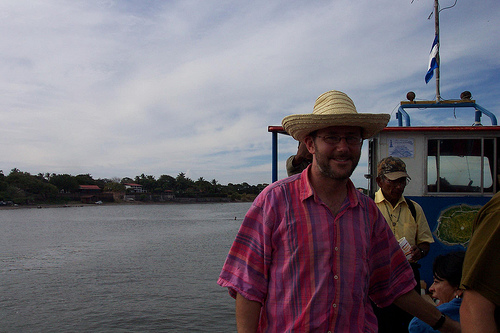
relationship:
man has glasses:
[217, 89, 461, 333] [319, 132, 364, 149]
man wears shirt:
[217, 89, 461, 333] [214, 160, 421, 332]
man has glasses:
[368, 152, 438, 327] [387, 178, 412, 183]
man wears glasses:
[368, 155, 438, 332] [383, 178, 410, 185]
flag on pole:
[423, 32, 440, 84] [431, 0, 440, 99]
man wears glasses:
[203, 68, 420, 329] [319, 132, 376, 146]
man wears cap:
[368, 152, 438, 327] [373, 155, 411, 180]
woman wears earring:
[403, 247, 464, 332] [453, 293, 459, 299]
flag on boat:
[422, 33, 441, 91] [260, 71, 494, 306]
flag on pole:
[424, 32, 436, 82] [436, 5, 441, 107]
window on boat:
[421, 147, 488, 192] [302, 83, 492, 316]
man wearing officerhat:
[203, 68, 420, 329] [281, 89, 391, 140]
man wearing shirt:
[203, 68, 420, 329] [214, 160, 421, 332]